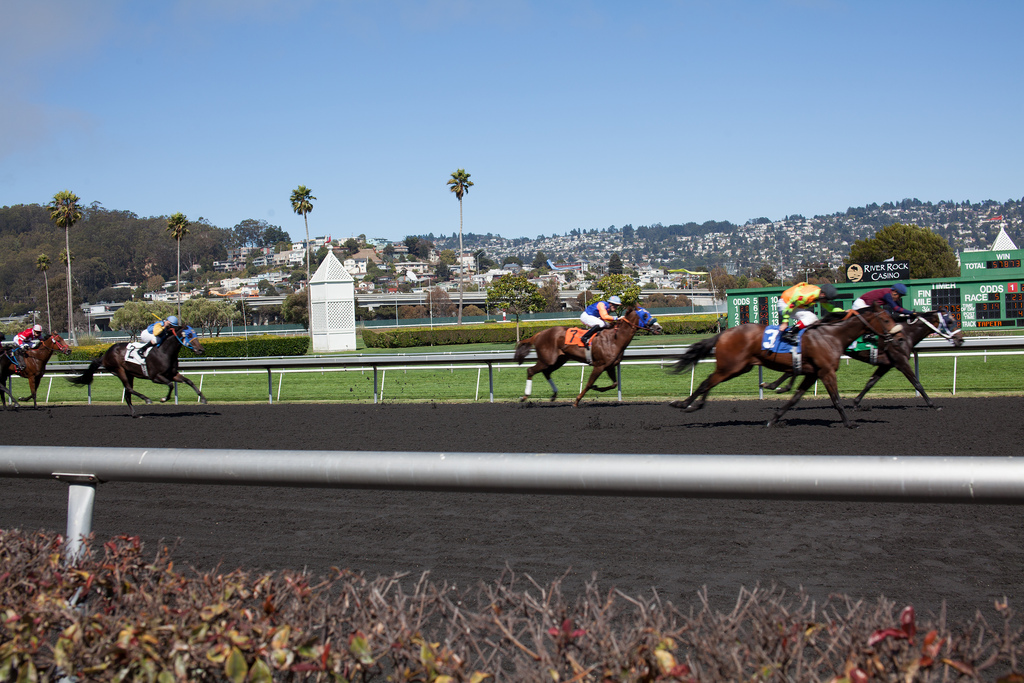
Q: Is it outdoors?
A: Yes, it is outdoors.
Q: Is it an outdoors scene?
A: Yes, it is outdoors.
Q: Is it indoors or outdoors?
A: It is outdoors.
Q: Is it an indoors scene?
A: No, it is outdoors.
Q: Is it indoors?
A: No, it is outdoors.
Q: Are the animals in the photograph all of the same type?
A: Yes, all the animals are horses.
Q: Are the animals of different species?
A: No, all the animals are horses.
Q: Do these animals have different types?
A: No, all the animals are horses.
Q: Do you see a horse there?
A: Yes, there is a horse.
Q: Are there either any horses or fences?
A: Yes, there is a horse.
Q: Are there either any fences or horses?
A: Yes, there is a horse.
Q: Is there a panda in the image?
A: No, there are no pandas.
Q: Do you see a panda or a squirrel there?
A: No, there are no pandas or squirrels.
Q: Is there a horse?
A: Yes, there is a horse.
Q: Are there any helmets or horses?
A: Yes, there is a horse.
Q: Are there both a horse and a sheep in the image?
A: No, there is a horse but no sheep.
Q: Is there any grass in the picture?
A: Yes, there is grass.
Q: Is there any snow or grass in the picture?
A: Yes, there is grass.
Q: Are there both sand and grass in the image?
A: No, there is grass but no sand.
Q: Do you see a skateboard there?
A: No, there are no skateboards.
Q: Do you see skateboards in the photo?
A: No, there are no skateboards.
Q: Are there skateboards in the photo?
A: No, there are no skateboards.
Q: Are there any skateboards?
A: No, there are no skateboards.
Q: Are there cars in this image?
A: No, there are no cars.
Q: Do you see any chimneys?
A: No, there are no chimneys.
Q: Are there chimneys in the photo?
A: No, there are no chimneys.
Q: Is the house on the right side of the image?
A: Yes, the house is on the right of the image.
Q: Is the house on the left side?
A: No, the house is on the right of the image.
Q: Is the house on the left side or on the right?
A: The house is on the right of the image.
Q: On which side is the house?
A: The house is on the right of the image.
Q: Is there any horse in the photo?
A: Yes, there are horses.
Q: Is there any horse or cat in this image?
A: Yes, there are horses.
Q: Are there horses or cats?
A: Yes, there are horses.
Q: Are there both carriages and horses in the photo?
A: No, there are horses but no carriages.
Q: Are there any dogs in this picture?
A: No, there are no dogs.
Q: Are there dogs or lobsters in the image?
A: No, there are no dogs or lobsters.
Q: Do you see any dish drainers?
A: No, there are no dish drainers.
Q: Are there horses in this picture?
A: Yes, there are horses.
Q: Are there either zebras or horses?
A: Yes, there are horses.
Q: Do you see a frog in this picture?
A: No, there are no frogs.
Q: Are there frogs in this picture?
A: No, there are no frogs.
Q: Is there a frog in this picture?
A: No, there are no frogs.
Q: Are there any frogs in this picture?
A: No, there are no frogs.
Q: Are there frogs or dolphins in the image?
A: No, there are no frogs or dolphins.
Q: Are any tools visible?
A: No, there are no tools.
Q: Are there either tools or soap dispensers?
A: No, there are no tools or soap dispensers.